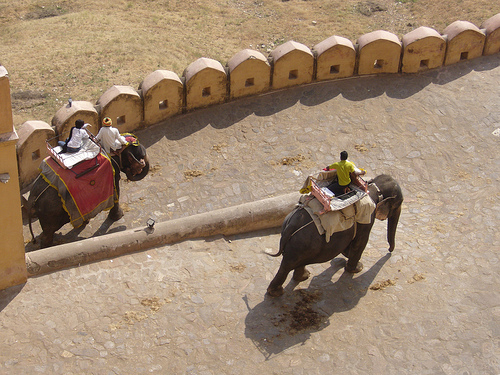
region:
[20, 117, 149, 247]
elephant with a red blanket on it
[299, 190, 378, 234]
elephant with a white blanket on it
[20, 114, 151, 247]
elephant with two peopel on its back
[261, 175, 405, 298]
elephant with one person on it's back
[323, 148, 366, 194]
man in a yellow shirt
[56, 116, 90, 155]
woman in a white shirt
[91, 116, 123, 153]
man in a hat with a white shirt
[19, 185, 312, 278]
piece of concrete in the ground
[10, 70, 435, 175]
concrete wall to contain the elephants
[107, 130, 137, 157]
red cloth on the elephant's head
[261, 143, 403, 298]
a man in yellow riding an elephant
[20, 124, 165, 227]
two people riding an elephant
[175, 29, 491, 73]
concrete pillars on the side of the pen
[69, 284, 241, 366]
tan dirt and rocks of the ground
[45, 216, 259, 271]
large wooden post laid on the ground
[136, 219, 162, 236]
a light attached to the post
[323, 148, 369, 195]
a man in a yellow shirt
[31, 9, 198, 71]
yellow grass outside of the pen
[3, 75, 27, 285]
yellow pole next to the pen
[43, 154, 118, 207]
red blanket laid on the elephant's back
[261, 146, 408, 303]
A young boy with a yellow shirt on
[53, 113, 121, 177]
A young boy with a white shirt on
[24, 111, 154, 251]
A person leading an elephant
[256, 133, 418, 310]
Young child riding on the back of an elephant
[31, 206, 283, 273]
A divider in the ground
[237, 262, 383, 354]
The elephant's shadow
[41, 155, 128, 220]
Red blanket on back of elephany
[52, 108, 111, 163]
Wire basket on the back of elephant with young boy in it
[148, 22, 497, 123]
Stones with holes in the middle creating an edge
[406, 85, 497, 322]
Dirt walk way for the elephants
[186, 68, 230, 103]
part of concrete enclosure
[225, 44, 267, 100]
part of concrete enclosure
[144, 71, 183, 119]
part of concrete enclosure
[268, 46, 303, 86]
part of concrete enclosure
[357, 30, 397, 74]
part of concrete enclosure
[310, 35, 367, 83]
part of concrete enclosure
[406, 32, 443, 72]
part of concrete enclosure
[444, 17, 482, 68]
part of concrete enclosure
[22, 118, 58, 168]
part of concrete enclosure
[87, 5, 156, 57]
this is the ground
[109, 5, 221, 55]
the ground is sandy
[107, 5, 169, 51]
the sand is brown in color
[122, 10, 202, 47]
the sand is stony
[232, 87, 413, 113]
this is the shadow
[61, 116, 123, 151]
these are two people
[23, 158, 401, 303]
these are two elephants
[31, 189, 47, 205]
the elephant is grey in color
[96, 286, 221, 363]
this is a road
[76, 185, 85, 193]
the carpet is red in color